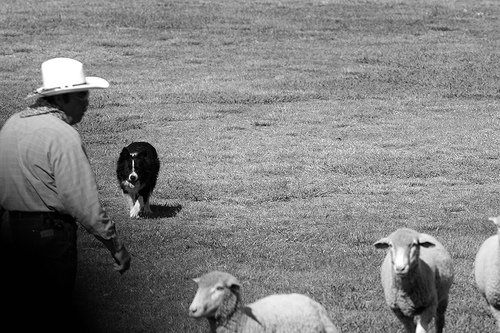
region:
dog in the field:
[108, 130, 173, 210]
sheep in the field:
[359, 200, 462, 327]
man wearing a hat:
[19, 59, 112, 101]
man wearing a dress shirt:
[1, 88, 128, 240]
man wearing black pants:
[2, 209, 87, 331]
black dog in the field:
[101, 128, 176, 224]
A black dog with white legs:
[115, 140, 158, 217]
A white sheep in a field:
[373, 222, 455, 327]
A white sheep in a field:
[183, 268, 333, 332]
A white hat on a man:
[26, 57, 108, 98]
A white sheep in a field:
[470, 213, 498, 327]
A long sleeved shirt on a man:
[0, 108, 107, 251]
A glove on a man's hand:
[93, 214, 131, 271]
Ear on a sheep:
[372, 236, 387, 248]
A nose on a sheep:
[190, 305, 199, 317]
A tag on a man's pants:
[37, 224, 60, 238]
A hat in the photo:
[27, 53, 115, 103]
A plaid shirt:
[20, 124, 95, 206]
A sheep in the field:
[146, 209, 498, 331]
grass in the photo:
[215, 82, 347, 183]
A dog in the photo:
[107, 137, 179, 214]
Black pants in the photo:
[25, 218, 87, 325]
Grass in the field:
[207, 55, 341, 196]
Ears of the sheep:
[362, 227, 439, 252]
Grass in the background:
[209, 69, 321, 141]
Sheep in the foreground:
[178, 224, 497, 329]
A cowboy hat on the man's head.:
[21, 55, 107, 100]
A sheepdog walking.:
[115, 140, 160, 215]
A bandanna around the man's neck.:
[15, 100, 66, 120]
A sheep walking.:
[371, 225, 451, 330]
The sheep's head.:
[370, 225, 430, 275]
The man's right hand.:
[110, 245, 125, 275]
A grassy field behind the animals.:
[160, 0, 497, 210]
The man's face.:
[65, 89, 91, 125]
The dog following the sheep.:
[116, 138, 498, 331]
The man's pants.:
[1, 208, 78, 331]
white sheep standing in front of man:
[182, 258, 354, 332]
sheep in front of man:
[371, 224, 456, 327]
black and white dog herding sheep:
[112, 138, 167, 218]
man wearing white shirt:
[6, 107, 116, 249]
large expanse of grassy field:
[8, 5, 497, 321]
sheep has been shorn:
[175, 263, 332, 326]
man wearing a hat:
[0, 51, 120, 301]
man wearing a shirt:
[0, 50, 115, 290]